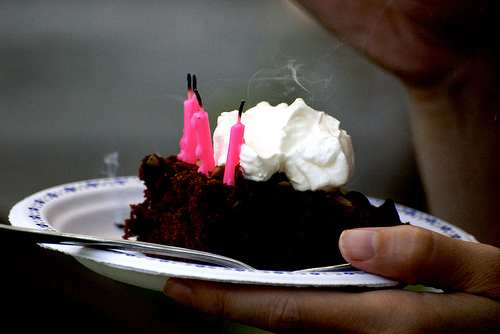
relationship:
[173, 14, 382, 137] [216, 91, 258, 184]
smoke above candle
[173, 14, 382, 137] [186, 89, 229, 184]
smoke above candle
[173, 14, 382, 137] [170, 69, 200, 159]
smoke above candle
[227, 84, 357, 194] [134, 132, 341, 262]
whipped cream on top of cake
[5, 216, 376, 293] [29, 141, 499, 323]
silver fork on top of plate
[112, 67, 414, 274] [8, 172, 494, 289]
cake on top of paper plate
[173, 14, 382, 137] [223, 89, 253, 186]
smoke above candles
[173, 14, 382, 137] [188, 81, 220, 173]
smoke above candles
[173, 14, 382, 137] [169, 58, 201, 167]
smoke above candles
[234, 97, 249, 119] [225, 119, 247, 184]
string attached on candle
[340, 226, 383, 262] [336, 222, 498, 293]
fingernail attached on thumb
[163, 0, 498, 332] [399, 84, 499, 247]
person has neck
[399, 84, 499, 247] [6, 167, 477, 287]
neck near plate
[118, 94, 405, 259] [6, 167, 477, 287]
cake on plate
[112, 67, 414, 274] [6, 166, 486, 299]
cake on plate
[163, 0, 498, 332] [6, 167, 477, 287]
person holding plate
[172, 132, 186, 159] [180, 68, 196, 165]
melted wax on candle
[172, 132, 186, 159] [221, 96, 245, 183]
melted wax on candle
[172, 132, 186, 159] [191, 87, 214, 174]
melted wax on candle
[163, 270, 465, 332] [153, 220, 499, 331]
finger on hand